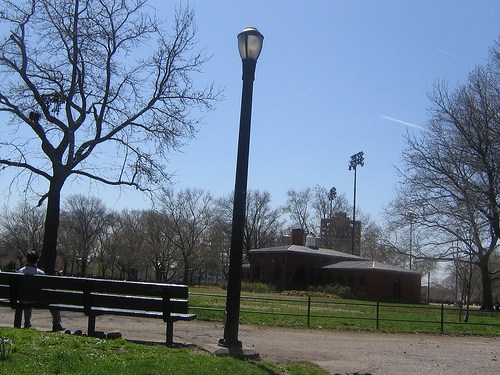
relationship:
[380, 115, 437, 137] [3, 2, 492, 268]
marking in sky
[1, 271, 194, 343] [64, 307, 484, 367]
bench near walkway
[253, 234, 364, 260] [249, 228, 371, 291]
roof on building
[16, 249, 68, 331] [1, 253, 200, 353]
man on bench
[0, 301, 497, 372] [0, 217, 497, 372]
walkway in park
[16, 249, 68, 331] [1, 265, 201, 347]
man on bench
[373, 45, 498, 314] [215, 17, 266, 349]
tree to right of light pole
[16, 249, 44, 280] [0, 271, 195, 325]
man sitting on bench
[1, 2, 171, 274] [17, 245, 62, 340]
tree in front of man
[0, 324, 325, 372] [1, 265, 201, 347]
area behind bench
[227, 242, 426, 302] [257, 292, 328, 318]
building across from grass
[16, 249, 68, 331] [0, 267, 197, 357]
man sitting on bench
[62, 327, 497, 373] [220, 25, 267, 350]
road on right of light pole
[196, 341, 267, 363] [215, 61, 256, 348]
cement block under light pole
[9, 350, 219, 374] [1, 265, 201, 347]
grass behind bench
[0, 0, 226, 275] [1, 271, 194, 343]
tree in front of bench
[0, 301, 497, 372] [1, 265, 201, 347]
walkway in front of bench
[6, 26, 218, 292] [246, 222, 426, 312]
trees near building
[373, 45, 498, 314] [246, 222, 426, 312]
tree near building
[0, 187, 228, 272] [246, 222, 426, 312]
trees near building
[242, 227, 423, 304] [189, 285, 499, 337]
structure on grass